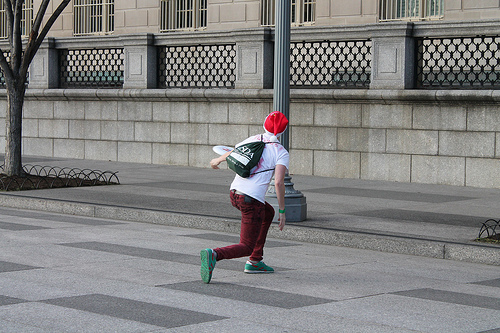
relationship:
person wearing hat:
[194, 107, 293, 281] [262, 102, 291, 145]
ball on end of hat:
[266, 133, 279, 143] [261, 108, 291, 145]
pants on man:
[195, 179, 289, 279] [184, 83, 307, 298]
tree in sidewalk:
[0, 25, 64, 185] [44, 167, 211, 320]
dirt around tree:
[13, 146, 78, 196] [10, 12, 80, 189]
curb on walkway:
[90, 149, 405, 286] [118, 145, 389, 272]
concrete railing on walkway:
[140, 22, 351, 105] [136, 143, 434, 265]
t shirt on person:
[224, 123, 288, 210] [194, 107, 293, 281]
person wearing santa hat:
[194, 107, 293, 281] [257, 102, 296, 133]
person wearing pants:
[194, 107, 293, 281] [219, 186, 277, 286]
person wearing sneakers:
[194, 107, 293, 281] [184, 244, 292, 284]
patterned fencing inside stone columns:
[85, 22, 456, 121] [154, 14, 394, 94]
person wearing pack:
[194, 107, 293, 281] [223, 140, 297, 178]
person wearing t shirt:
[194, 107, 293, 281] [224, 123, 284, 210]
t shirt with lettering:
[224, 123, 284, 210] [244, 136, 281, 174]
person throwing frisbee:
[194, 107, 293, 281] [264, 190, 292, 226]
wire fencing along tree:
[31, 150, 128, 196] [1, 1, 121, 196]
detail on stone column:
[123, 46, 147, 76] [121, 23, 151, 105]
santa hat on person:
[261, 109, 290, 139] [203, 98, 310, 287]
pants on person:
[195, 179, 289, 279] [195, 96, 304, 285]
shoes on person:
[188, 247, 275, 278] [194, 90, 314, 306]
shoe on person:
[165, 240, 285, 284] [197, 88, 306, 291]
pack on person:
[231, 143, 264, 179] [191, 98, 302, 298]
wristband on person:
[278, 192, 304, 212] [194, 107, 293, 281]